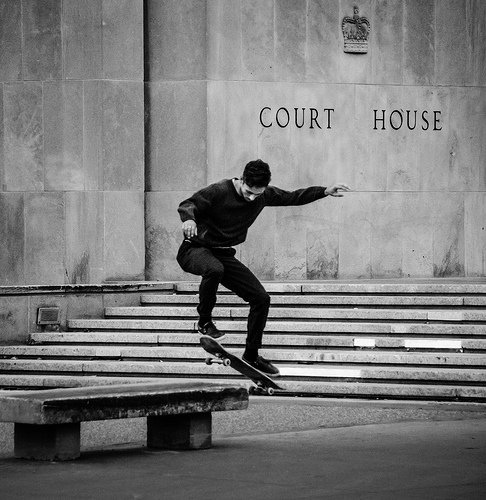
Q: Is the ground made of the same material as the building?
A: Yes, both the ground and the building are made of concrete.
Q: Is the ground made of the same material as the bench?
A: Yes, both the ground and the bench are made of cement.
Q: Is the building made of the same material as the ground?
A: Yes, both the building and the ground are made of cement.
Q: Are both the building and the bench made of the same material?
A: Yes, both the building and the bench are made of concrete.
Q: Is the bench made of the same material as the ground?
A: Yes, both the bench and the ground are made of cement.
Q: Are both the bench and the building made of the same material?
A: Yes, both the bench and the building are made of concrete.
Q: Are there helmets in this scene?
A: No, there are no helmets.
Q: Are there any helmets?
A: No, there are no helmets.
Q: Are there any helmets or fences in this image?
A: No, there are no helmets or fences.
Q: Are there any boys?
A: No, there are no boys.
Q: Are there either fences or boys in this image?
A: No, there are no boys or fences.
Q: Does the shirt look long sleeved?
A: Yes, the shirt is long sleeved.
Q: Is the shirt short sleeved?
A: No, the shirt is long sleeved.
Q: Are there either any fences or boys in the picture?
A: No, there are no boys or fences.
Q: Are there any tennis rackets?
A: No, there are no tennis rackets.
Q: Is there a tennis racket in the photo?
A: No, there are no rackets.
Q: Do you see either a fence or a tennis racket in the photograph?
A: No, there are no rackets or fences.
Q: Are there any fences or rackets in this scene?
A: No, there are no rackets or fences.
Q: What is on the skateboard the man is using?
A: The sneakers are on the skateboard.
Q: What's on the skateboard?
A: The sneakers are on the skateboard.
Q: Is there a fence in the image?
A: No, there are no fences.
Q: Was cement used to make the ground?
A: Yes, the ground is made of cement.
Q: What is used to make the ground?
A: The ground is made of cement.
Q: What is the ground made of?
A: The ground is made of concrete.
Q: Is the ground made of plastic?
A: No, the ground is made of cement.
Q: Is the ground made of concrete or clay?
A: The ground is made of concrete.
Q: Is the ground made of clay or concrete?
A: The ground is made of concrete.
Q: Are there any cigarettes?
A: No, there are no cigarettes.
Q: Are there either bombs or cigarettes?
A: No, there are no cigarettes or bombs.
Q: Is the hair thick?
A: Yes, the hair is thick.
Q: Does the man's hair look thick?
A: Yes, the hair is thick.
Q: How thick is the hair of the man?
A: The hair is thick.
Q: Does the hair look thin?
A: No, the hair is thick.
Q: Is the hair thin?
A: No, the hair is thick.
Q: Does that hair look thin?
A: No, the hair is thick.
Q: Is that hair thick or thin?
A: The hair is thick.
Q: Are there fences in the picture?
A: No, there are no fences.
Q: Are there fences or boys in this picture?
A: No, there are no fences or boys.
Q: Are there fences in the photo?
A: No, there are no fences.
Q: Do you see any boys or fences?
A: No, there are no fences or boys.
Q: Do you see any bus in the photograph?
A: No, there are no buses.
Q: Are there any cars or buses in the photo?
A: No, there are no buses or cars.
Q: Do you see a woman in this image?
A: No, there are no women.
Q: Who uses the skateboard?
A: The man uses the skateboard.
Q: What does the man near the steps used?
A: The man uses a skateboard.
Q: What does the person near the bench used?
A: The man uses a skateboard.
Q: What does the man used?
A: The man uses a skateboard.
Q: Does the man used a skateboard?
A: Yes, the man uses a skateboard.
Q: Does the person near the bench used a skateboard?
A: Yes, the man uses a skateboard.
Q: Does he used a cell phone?
A: No, the man uses a skateboard.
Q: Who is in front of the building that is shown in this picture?
A: The man is in front of the building.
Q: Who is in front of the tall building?
A: The man is in front of the building.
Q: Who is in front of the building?
A: The man is in front of the building.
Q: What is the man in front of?
A: The man is in front of the building.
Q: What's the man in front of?
A: The man is in front of the building.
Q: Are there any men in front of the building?
A: Yes, there is a man in front of the building.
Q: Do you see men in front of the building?
A: Yes, there is a man in front of the building.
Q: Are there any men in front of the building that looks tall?
A: Yes, there is a man in front of the building.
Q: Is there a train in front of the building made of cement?
A: No, there is a man in front of the building.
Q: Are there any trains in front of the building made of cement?
A: No, there is a man in front of the building.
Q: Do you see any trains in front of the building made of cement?
A: No, there is a man in front of the building.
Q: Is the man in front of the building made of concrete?
A: Yes, the man is in front of the building.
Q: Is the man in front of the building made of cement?
A: Yes, the man is in front of the building.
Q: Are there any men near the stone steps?
A: Yes, there is a man near the steps.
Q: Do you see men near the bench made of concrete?
A: Yes, there is a man near the bench.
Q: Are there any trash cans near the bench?
A: No, there is a man near the bench.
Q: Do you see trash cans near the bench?
A: No, there is a man near the bench.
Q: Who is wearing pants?
A: The man is wearing pants.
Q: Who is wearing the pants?
A: The man is wearing pants.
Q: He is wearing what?
A: The man is wearing pants.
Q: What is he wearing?
A: The man is wearing pants.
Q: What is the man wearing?
A: The man is wearing pants.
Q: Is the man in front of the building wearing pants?
A: Yes, the man is wearing pants.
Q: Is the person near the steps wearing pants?
A: Yes, the man is wearing pants.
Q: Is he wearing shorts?
A: No, the man is wearing pants.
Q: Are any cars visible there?
A: No, there are no cars.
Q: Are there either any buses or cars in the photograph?
A: No, there are no cars or buses.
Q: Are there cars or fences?
A: No, there are no cars or fences.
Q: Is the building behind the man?
A: Yes, the building is behind the man.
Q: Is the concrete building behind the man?
A: Yes, the building is behind the man.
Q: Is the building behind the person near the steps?
A: Yes, the building is behind the man.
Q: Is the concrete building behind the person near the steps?
A: Yes, the building is behind the man.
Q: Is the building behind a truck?
A: No, the building is behind the man.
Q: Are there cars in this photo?
A: No, there are no cars.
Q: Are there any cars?
A: No, there are no cars.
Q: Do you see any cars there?
A: No, there are no cars.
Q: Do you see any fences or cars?
A: No, there are no cars or fences.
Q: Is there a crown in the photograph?
A: Yes, there is a crown.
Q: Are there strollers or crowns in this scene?
A: Yes, there is a crown.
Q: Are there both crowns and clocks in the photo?
A: No, there is a crown but no clocks.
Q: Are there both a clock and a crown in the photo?
A: No, there is a crown but no clocks.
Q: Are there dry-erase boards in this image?
A: No, there are no dry-erase boards.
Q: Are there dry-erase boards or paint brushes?
A: No, there are no dry-erase boards or paint brushes.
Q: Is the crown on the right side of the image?
A: Yes, the crown is on the right of the image.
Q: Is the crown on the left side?
A: No, the crown is on the right of the image.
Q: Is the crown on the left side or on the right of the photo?
A: The crown is on the right of the image.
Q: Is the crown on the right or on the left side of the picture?
A: The crown is on the right of the image.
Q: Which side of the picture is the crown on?
A: The crown is on the right of the image.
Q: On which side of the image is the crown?
A: The crown is on the right of the image.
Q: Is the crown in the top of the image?
A: Yes, the crown is in the top of the image.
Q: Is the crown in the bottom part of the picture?
A: No, the crown is in the top of the image.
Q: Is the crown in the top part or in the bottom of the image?
A: The crown is in the top of the image.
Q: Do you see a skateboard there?
A: Yes, there is a skateboard.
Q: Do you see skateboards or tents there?
A: Yes, there is a skateboard.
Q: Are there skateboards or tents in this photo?
A: Yes, there is a skateboard.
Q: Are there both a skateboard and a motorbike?
A: No, there is a skateboard but no motorcycles.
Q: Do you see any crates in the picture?
A: No, there are no crates.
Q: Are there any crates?
A: No, there are no crates.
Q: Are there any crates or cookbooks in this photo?
A: No, there are no crates or cookbooks.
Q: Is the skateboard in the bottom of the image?
A: Yes, the skateboard is in the bottom of the image.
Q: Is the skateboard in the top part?
A: No, the skateboard is in the bottom of the image.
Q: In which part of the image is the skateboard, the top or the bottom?
A: The skateboard is in the bottom of the image.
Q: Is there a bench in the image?
A: Yes, there is a bench.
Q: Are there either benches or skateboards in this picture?
A: Yes, there is a bench.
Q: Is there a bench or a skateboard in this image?
A: Yes, there is a bench.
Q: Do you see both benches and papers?
A: No, there is a bench but no papers.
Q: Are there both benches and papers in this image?
A: No, there is a bench but no papers.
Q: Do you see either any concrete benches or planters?
A: Yes, there is a concrete bench.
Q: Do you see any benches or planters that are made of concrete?
A: Yes, the bench is made of concrete.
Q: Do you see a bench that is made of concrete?
A: Yes, there is a bench that is made of concrete.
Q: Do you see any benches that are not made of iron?
A: Yes, there is a bench that is made of concrete.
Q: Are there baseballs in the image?
A: No, there are no baseballs.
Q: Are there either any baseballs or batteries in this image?
A: No, there are no baseballs or batteries.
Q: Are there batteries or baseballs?
A: No, there are no baseballs or batteries.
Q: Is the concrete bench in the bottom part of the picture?
A: Yes, the bench is in the bottom of the image.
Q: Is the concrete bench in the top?
A: No, the bench is in the bottom of the image.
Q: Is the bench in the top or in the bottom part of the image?
A: The bench is in the bottom of the image.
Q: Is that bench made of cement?
A: Yes, the bench is made of cement.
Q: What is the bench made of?
A: The bench is made of concrete.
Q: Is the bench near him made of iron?
A: No, the bench is made of cement.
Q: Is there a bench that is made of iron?
A: No, there is a bench but it is made of cement.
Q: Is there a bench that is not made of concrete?
A: No, there is a bench but it is made of concrete.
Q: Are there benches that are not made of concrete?
A: No, there is a bench but it is made of concrete.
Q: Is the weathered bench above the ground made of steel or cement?
A: The bench is made of cement.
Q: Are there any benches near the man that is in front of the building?
A: Yes, there is a bench near the man.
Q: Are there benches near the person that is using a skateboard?
A: Yes, there is a bench near the man.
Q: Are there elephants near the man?
A: No, there is a bench near the man.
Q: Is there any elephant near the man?
A: No, there is a bench near the man.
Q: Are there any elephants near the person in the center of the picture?
A: No, there is a bench near the man.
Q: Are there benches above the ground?
A: Yes, there is a bench above the ground.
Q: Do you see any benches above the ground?
A: Yes, there is a bench above the ground.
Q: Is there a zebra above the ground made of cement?
A: No, there is a bench above the ground.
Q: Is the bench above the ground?
A: Yes, the bench is above the ground.